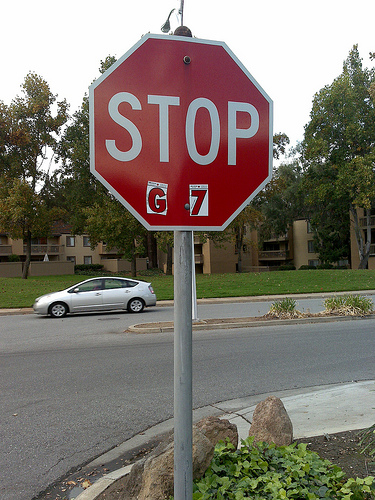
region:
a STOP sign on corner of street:
[75, 25, 281, 248]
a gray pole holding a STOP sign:
[76, 14, 280, 495]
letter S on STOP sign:
[99, 82, 149, 168]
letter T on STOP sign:
[140, 83, 188, 170]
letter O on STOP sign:
[182, 91, 224, 167]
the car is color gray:
[24, 268, 165, 322]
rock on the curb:
[235, 391, 299, 451]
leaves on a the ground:
[213, 437, 331, 499]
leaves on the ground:
[53, 467, 91, 492]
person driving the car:
[85, 279, 103, 291]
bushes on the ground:
[260, 295, 370, 323]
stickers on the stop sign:
[135, 173, 221, 221]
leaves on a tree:
[307, 54, 371, 180]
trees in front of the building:
[309, 56, 372, 269]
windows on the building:
[62, 228, 94, 251]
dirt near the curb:
[310, 432, 362, 474]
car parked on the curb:
[34, 262, 174, 327]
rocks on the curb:
[250, 392, 294, 454]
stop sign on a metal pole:
[80, 22, 275, 241]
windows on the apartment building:
[59, 227, 98, 248]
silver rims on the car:
[131, 295, 142, 312]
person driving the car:
[83, 275, 98, 290]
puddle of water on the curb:
[56, 471, 81, 497]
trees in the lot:
[11, 110, 48, 272]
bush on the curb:
[267, 291, 313, 329]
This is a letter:
[96, 80, 146, 169]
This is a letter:
[144, 85, 180, 175]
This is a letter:
[180, 87, 224, 170]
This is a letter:
[221, 91, 262, 172]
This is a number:
[183, 180, 215, 218]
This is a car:
[26, 269, 164, 327]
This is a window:
[65, 232, 76, 247]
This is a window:
[76, 228, 97, 248]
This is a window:
[80, 251, 99, 276]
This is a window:
[304, 234, 323, 257]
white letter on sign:
[103, 90, 145, 169]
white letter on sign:
[148, 92, 181, 167]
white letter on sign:
[186, 96, 220, 166]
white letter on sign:
[226, 100, 258, 168]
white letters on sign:
[104, 91, 258, 164]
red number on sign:
[190, 189, 208, 216]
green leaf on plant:
[196, 481, 209, 491]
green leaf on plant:
[259, 460, 268, 471]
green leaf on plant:
[285, 487, 299, 496]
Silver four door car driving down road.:
[23, 265, 162, 328]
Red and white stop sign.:
[80, 14, 285, 253]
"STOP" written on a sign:
[96, 78, 264, 177]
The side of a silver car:
[24, 266, 163, 319]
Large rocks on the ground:
[132, 385, 298, 494]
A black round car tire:
[39, 294, 74, 319]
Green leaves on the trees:
[0, 37, 370, 278]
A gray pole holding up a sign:
[165, 225, 202, 496]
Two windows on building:
[57, 225, 93, 255]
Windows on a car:
[60, 270, 140, 296]